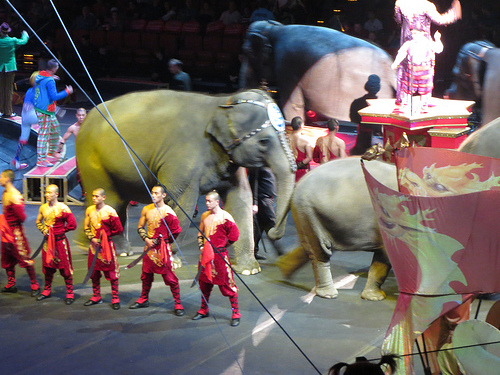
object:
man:
[192, 192, 240, 327]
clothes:
[197, 210, 240, 319]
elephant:
[75, 88, 300, 276]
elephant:
[240, 20, 398, 125]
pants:
[0, 71, 15, 116]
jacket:
[33, 70, 70, 118]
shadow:
[243, 21, 288, 108]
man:
[57, 108, 89, 152]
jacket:
[0, 30, 29, 72]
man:
[169, 59, 191, 91]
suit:
[171, 70, 192, 91]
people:
[129, 185, 182, 315]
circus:
[1, 0, 499, 373]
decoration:
[224, 88, 298, 172]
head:
[221, 89, 286, 168]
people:
[0, 169, 41, 296]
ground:
[1, 320, 174, 372]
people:
[391, 29, 444, 116]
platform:
[358, 96, 476, 149]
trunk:
[261, 153, 295, 239]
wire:
[8, 0, 325, 374]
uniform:
[0, 190, 40, 290]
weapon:
[30, 234, 48, 259]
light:
[285, 48, 397, 124]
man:
[35, 59, 75, 168]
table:
[0, 115, 85, 205]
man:
[0, 22, 30, 118]